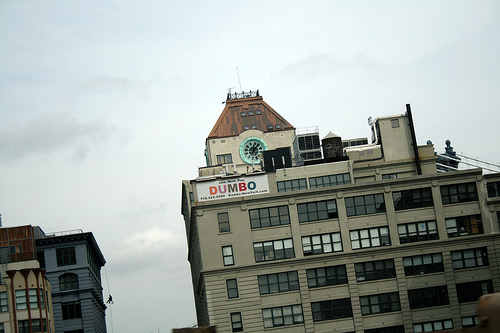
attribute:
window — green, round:
[234, 134, 274, 178]